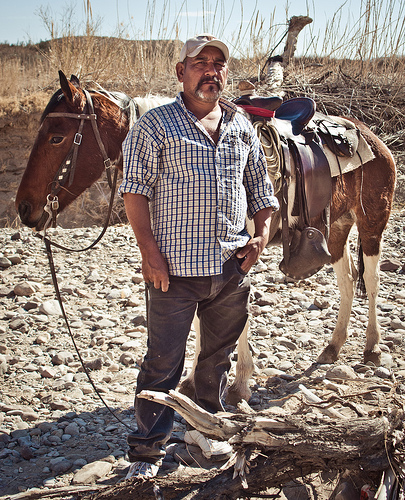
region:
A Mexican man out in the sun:
[181, 33, 229, 111]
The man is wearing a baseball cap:
[178, 32, 230, 103]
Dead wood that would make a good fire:
[151, 389, 389, 457]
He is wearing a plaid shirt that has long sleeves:
[166, 41, 266, 241]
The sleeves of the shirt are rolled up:
[107, 150, 163, 210]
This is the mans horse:
[39, 67, 205, 268]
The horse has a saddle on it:
[243, 86, 343, 131]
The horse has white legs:
[323, 163, 385, 353]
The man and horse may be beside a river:
[23, 219, 130, 333]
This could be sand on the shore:
[15, 297, 98, 430]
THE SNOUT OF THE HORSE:
[3, 184, 107, 241]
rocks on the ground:
[37, 420, 102, 444]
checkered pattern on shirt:
[162, 170, 209, 261]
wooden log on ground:
[253, 416, 355, 470]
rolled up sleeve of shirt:
[116, 178, 155, 211]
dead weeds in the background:
[48, 30, 133, 75]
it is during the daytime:
[62, 4, 141, 38]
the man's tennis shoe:
[119, 457, 162, 484]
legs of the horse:
[324, 245, 378, 373]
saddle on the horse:
[276, 127, 330, 283]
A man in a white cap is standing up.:
[118, 35, 278, 492]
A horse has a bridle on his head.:
[13, 82, 125, 254]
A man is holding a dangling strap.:
[44, 243, 149, 442]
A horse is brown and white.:
[15, 70, 395, 369]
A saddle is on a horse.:
[232, 86, 373, 286]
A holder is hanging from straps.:
[267, 134, 339, 287]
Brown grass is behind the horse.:
[1, 1, 402, 161]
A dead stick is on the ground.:
[42, 391, 390, 499]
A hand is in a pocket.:
[234, 232, 266, 292]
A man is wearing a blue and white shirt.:
[119, 94, 281, 278]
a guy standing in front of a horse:
[97, 33, 318, 379]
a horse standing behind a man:
[35, 75, 387, 177]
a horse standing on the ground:
[31, 89, 403, 290]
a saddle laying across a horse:
[239, 93, 362, 188]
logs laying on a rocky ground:
[207, 405, 402, 469]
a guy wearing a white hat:
[171, 38, 253, 62]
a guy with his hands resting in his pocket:
[192, 213, 310, 279]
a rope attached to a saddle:
[250, 117, 315, 195]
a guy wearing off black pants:
[113, 323, 258, 423]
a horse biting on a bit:
[9, 157, 88, 281]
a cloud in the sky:
[179, 10, 221, 18]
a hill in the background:
[15, 29, 192, 59]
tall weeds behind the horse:
[32, 7, 395, 74]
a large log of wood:
[133, 378, 368, 488]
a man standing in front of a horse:
[137, 33, 278, 412]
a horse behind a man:
[19, 73, 402, 351]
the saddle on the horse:
[243, 87, 338, 276]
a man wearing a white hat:
[134, 36, 268, 283]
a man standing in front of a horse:
[24, 40, 401, 363]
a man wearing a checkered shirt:
[119, 32, 277, 292]